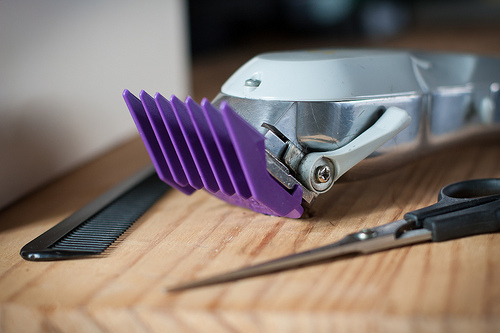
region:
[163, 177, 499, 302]
black and gray scissors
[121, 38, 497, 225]
razor machine on a table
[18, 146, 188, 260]
black comb on table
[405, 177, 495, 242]
black handle of scissors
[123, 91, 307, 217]
purple blade of razor machine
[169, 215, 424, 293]
metal part of scissors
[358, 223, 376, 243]
little screw on scissors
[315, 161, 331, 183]
little screw on razor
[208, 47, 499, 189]
gray and white razor machine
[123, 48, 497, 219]
purple and white razor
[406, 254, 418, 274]
part of a table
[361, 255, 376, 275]
part of a scissor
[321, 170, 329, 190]
part of a machine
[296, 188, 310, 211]
edge of a table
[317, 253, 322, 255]
part of a knife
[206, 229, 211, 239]
edge of a table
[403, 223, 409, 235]
part of a pedal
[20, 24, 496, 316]
things to cut hair with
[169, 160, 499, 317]
black hair cutting scissors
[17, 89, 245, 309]
a black fine tooth comb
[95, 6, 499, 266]
silver electric razor for cutting hair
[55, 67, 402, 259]
purple razor guard for cutting hair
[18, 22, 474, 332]
comb, electric razor, and scissors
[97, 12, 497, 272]
hair cutting buzzers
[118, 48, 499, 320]
small pair of hair cutting scissors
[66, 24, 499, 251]
buzzers sitting upside down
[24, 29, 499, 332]
hair cutting items on a wooden counter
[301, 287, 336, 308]
Small part of the wooden table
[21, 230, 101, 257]
Top section of the black comb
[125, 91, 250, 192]
Large purple clip used for razor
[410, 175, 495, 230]
Bottom black section of the scissors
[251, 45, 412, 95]
Gray section of the razor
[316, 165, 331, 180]
Silver screw in the razor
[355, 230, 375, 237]
Silver screw on scissors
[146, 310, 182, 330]
Edge of wooden table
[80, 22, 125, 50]
Small part of white wall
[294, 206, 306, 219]
Small tiny part of purple clip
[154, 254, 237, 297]
tip of metal shiny scissors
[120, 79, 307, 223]
purple plastic hair clipper guide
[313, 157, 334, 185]
one round shiny metal screw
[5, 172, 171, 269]
one long black plastic comb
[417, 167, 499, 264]
black plastic scissor handles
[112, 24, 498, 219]
one shiny metal hair clippers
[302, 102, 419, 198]
one gray plastic hair clipper lever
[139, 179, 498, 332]
pair of scissors on wooden table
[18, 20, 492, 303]
hair cutting supplies on table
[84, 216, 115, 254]
several black comb teeth